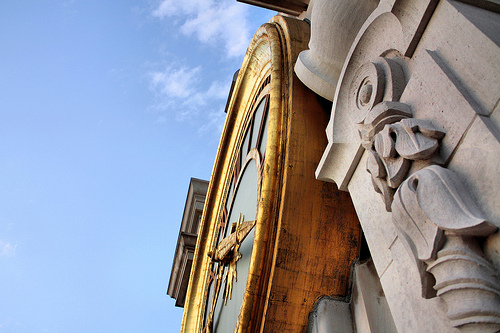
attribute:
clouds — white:
[144, 57, 232, 141]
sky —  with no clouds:
[2, 0, 164, 331]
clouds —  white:
[151, 3, 248, 97]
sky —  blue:
[1, 5, 196, 325]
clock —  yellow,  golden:
[179, 9, 311, 329]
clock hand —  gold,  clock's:
[211, 219, 253, 262]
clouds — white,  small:
[154, 3, 252, 55]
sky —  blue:
[4, 2, 214, 169]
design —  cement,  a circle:
[340, 60, 386, 127]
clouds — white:
[130, 6, 284, 179]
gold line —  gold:
[242, 111, 257, 149]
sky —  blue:
[32, 61, 172, 233]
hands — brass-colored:
[207, 208, 258, 290]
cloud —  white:
[156, 0, 251, 67]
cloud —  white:
[138, 58, 229, 133]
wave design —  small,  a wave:
[353, 117, 455, 204]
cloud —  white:
[154, 1, 251, 56]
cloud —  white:
[146, 60, 227, 129]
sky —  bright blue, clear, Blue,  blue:
[0, 1, 275, 331]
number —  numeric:
[225, 154, 243, 191]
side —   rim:
[272, 173, 358, 302]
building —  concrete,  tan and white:
[292, 0, 496, 330]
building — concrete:
[162, 3, 492, 331]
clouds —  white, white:
[147, 0, 253, 57]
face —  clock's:
[180, 27, 271, 330]